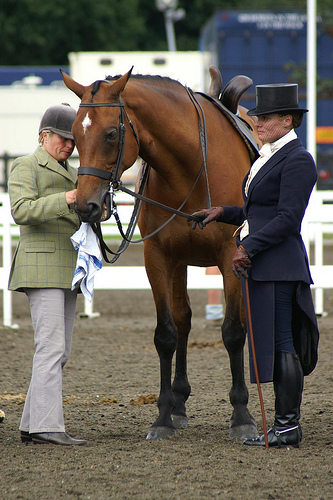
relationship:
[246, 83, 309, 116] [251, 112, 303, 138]
top hat on head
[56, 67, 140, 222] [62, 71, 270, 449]
head on horse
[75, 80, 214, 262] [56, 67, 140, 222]
harness on head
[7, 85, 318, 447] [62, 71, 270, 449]
people next to horse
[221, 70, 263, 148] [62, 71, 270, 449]
saddle on horse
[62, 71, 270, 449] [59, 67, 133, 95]
horse has ears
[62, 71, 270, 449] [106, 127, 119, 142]
horse has a left eye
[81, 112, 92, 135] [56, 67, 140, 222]
spot on head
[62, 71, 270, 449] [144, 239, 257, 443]
horse has legs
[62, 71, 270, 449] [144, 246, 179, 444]
horse front right leg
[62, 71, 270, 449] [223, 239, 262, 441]
horse front left leg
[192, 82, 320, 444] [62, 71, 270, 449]
woman standing next to horse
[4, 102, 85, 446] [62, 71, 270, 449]
woman standing next to horse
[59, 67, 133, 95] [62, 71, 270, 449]
ears on horse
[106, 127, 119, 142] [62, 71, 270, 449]
left eye on horse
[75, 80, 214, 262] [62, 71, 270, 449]
bridle on horse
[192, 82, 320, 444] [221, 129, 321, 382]
woman in a suit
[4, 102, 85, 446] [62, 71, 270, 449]
woman working on horse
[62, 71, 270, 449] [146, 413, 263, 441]
horse has hooves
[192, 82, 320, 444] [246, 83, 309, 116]
woman wearing a top hat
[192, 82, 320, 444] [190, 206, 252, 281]
woman wearing gloves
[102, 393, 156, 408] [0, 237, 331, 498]
dung on ground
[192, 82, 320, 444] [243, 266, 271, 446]
woman holding cane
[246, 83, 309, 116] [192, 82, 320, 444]
top hat on woman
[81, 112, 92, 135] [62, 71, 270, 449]
spot on horse